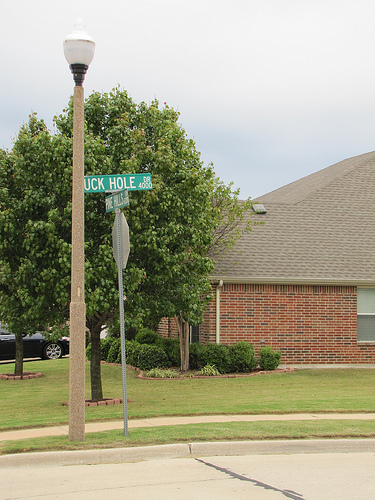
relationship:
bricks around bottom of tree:
[2, 370, 42, 380] [12, 334, 26, 374]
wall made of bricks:
[156, 285, 374, 364] [159, 283, 374, 364]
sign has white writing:
[85, 173, 153, 191] [86, 177, 152, 189]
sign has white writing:
[104, 190, 131, 211] [104, 190, 129, 208]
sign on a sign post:
[83, 173, 153, 194] [115, 208, 131, 439]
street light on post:
[63, 14, 97, 85] [68, 84, 88, 444]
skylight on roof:
[253, 202, 267, 215] [181, 149, 375, 283]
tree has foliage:
[1, 81, 267, 404] [1, 83, 267, 332]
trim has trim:
[356, 287, 374, 342] [356, 287, 374, 342]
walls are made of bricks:
[156, 285, 374, 364] [159, 283, 374, 364]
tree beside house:
[176, 158, 266, 373] [153, 150, 375, 368]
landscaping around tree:
[2, 370, 42, 380] [1, 107, 59, 375]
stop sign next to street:
[112, 211, 131, 268] [1, 449, 375, 498]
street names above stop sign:
[85, 172, 154, 213] [112, 211, 131, 268]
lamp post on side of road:
[63, 14, 97, 444] [1, 449, 375, 498]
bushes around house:
[85, 325, 280, 372] [153, 150, 375, 368]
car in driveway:
[1, 325, 70, 359] [1, 348, 104, 364]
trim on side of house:
[356, 287, 374, 342] [153, 150, 375, 368]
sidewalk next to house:
[1, 410, 374, 441] [153, 150, 375, 368]